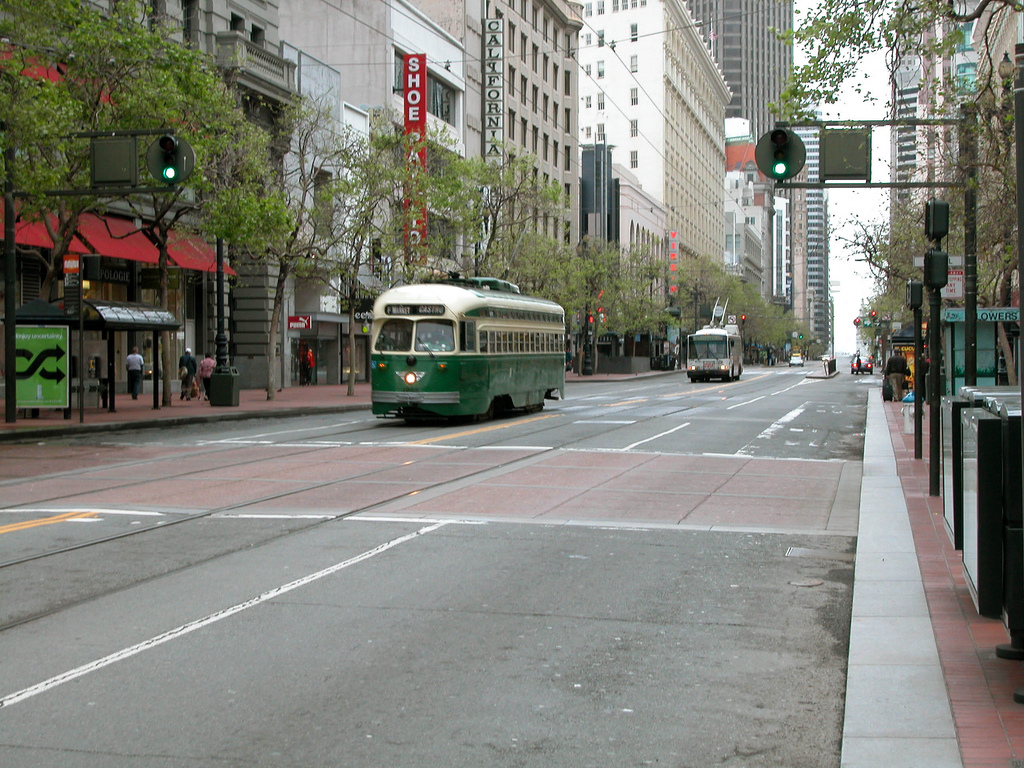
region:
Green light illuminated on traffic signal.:
[161, 164, 185, 184]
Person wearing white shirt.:
[120, 351, 149, 371]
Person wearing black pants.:
[123, 363, 144, 398]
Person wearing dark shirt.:
[170, 353, 200, 374]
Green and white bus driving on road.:
[364, 279, 573, 403]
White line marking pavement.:
[37, 524, 426, 711]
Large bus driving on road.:
[678, 323, 752, 385]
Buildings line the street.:
[68, 53, 816, 349]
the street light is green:
[764, 156, 793, 180]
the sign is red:
[398, 50, 433, 124]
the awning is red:
[94, 222, 152, 246]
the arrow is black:
[34, 338, 69, 371]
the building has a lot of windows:
[515, 32, 570, 138]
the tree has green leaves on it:
[103, 29, 192, 107]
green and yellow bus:
[320, 256, 576, 453]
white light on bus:
[382, 347, 441, 430]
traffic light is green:
[755, 125, 791, 174]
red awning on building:
[6, 204, 250, 269]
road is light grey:
[228, 552, 495, 683]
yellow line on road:
[1, 491, 104, 556]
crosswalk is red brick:
[74, 395, 820, 566]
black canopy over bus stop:
[60, 293, 220, 430]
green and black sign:
[3, 315, 76, 417]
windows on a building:
[384, 40, 477, 143]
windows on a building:
[499, 3, 520, 171]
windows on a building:
[515, 19, 532, 188]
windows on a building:
[528, 35, 545, 172]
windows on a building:
[539, 40, 555, 192]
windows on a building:
[582, 25, 615, 152]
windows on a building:
[622, 13, 657, 181]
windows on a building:
[664, 35, 707, 254]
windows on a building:
[694, 75, 726, 285]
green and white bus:
[361, 276, 570, 432]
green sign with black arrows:
[17, 306, 68, 417]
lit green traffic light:
[756, 118, 810, 189]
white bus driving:
[679, 293, 749, 386]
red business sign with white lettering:
[396, 47, 438, 275]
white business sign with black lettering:
[478, 12, 504, 165]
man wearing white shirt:
[124, 340, 145, 408]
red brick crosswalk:
[0, 442, 864, 529]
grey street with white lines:
[3, 374, 866, 767]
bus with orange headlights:
[361, 286, 576, 427]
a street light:
[764, 117, 958, 191]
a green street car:
[378, 284, 578, 403]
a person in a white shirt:
[125, 342, 139, 387]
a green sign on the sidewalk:
[22, 323, 68, 401]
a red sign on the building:
[398, 57, 421, 247]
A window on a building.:
[562, 144, 575, 179]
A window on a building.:
[561, 106, 571, 136]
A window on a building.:
[632, 84, 637, 111]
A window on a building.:
[631, 150, 641, 166]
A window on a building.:
[629, 21, 640, 48]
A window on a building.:
[553, 61, 564, 88]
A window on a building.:
[395, 59, 466, 124]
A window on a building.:
[518, 114, 528, 152]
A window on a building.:
[502, 103, 513, 141]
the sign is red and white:
[405, 54, 428, 276]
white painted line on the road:
[0, 525, 441, 716]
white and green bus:
[373, 278, 569, 415]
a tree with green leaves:
[8, 9, 281, 289]